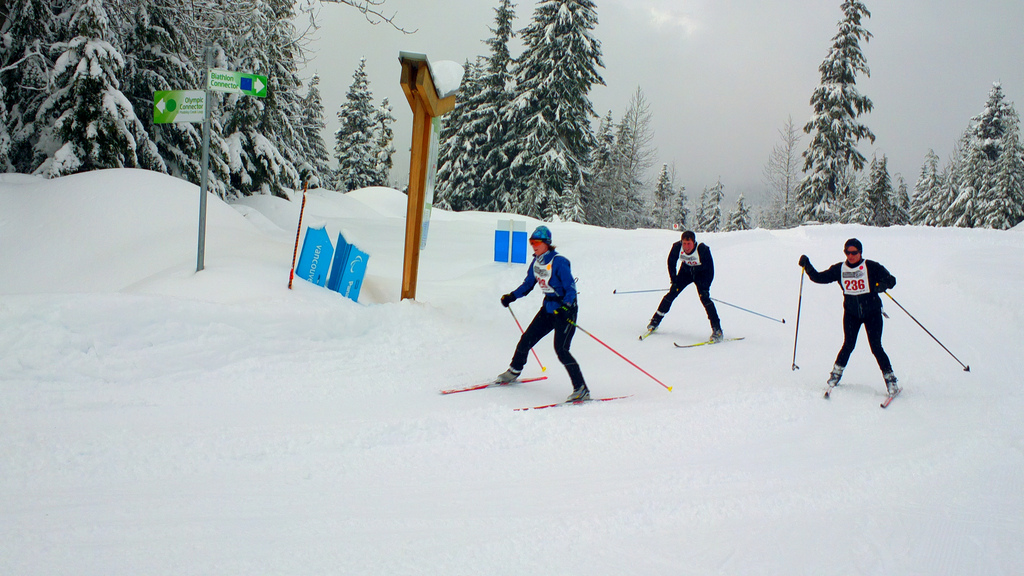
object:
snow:
[43, 192, 136, 276]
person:
[614, 231, 786, 351]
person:
[791, 236, 974, 409]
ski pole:
[710, 297, 786, 330]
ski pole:
[613, 289, 668, 294]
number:
[841, 279, 865, 290]